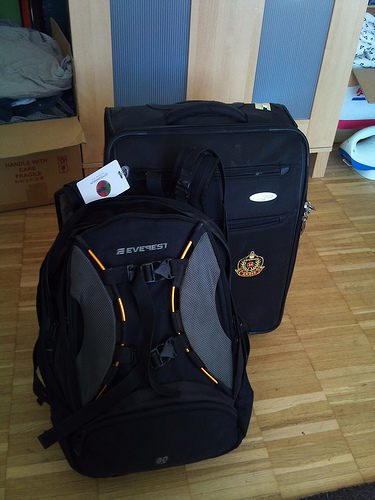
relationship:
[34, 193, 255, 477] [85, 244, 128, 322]
backpack with accent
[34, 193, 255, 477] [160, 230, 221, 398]
backpack with accent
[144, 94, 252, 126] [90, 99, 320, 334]
handle on suitcase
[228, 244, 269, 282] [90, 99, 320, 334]
emblem on suitcase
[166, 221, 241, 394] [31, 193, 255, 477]
zippered pocket on backpack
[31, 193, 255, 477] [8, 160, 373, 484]
backpack on floor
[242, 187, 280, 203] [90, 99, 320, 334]
decal on suitcase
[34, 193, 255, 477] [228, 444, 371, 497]
backpack on floor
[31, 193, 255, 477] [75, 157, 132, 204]
backpack with tag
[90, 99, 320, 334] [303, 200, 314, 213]
suitcase with zipper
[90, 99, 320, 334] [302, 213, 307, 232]
suitcase with zipper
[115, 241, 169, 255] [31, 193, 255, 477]
name on backpack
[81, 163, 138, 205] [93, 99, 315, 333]
tag on suitcase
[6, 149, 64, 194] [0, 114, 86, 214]
writing on box